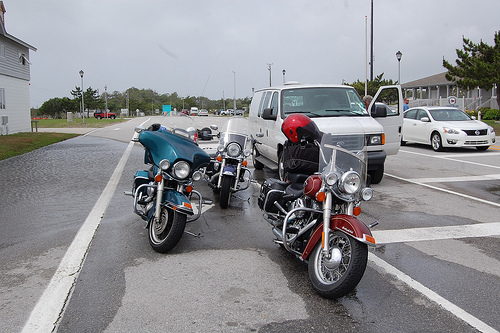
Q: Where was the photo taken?
A: It was taken at the street.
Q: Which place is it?
A: It is a street.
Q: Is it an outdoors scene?
A: Yes, it is outdoors.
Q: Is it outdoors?
A: Yes, it is outdoors.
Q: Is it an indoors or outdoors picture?
A: It is outdoors.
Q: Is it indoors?
A: No, it is outdoors.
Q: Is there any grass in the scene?
A: Yes, there is grass.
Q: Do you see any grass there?
A: Yes, there is grass.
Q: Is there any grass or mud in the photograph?
A: Yes, there is grass.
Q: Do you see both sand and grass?
A: No, there is grass but no sand.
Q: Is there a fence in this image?
A: No, there are no fences.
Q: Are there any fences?
A: No, there are no fences.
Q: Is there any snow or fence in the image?
A: No, there are no fences or snow.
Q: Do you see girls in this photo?
A: No, there are no girls.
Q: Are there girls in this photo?
A: No, there are no girls.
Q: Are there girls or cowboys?
A: No, there are no girls or cowboys.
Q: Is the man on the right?
A: Yes, the man is on the right of the image.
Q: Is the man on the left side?
A: No, the man is on the right of the image.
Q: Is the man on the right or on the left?
A: The man is on the right of the image.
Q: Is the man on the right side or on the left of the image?
A: The man is on the right of the image.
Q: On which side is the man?
A: The man is on the right of the image.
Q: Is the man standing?
A: Yes, the man is standing.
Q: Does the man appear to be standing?
A: Yes, the man is standing.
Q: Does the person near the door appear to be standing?
A: Yes, the man is standing.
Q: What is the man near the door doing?
A: The man is standing.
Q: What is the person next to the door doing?
A: The man is standing.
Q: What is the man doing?
A: The man is standing.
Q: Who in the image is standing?
A: The man is standing.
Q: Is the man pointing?
A: No, the man is standing.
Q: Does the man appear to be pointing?
A: No, the man is standing.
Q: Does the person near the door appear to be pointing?
A: No, the man is standing.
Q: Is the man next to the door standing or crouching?
A: The man is standing.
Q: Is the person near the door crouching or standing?
A: The man is standing.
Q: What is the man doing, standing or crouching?
A: The man is standing.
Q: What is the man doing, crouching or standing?
A: The man is standing.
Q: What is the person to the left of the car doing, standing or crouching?
A: The man is standing.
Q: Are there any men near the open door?
A: Yes, there is a man near the door.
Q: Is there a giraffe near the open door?
A: No, there is a man near the door.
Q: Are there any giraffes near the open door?
A: No, there is a man near the door.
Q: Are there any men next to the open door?
A: Yes, there is a man next to the door.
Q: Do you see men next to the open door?
A: Yes, there is a man next to the door.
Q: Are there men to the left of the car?
A: Yes, there is a man to the left of the car.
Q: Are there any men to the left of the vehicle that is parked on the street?
A: Yes, there is a man to the left of the car.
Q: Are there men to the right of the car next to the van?
A: No, the man is to the left of the car.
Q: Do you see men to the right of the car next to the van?
A: No, the man is to the left of the car.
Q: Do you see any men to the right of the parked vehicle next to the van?
A: No, the man is to the left of the car.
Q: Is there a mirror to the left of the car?
A: No, there is a man to the left of the car.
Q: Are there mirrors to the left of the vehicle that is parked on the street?
A: No, there is a man to the left of the car.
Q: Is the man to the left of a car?
A: Yes, the man is to the left of a car.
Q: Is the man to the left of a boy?
A: No, the man is to the left of a car.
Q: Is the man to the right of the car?
A: No, the man is to the left of the car.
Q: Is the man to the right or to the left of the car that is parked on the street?
A: The man is to the left of the car.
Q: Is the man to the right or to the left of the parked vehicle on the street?
A: The man is to the left of the car.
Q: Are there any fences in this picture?
A: No, there are no fences.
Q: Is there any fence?
A: No, there are no fences.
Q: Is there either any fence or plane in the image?
A: No, there are no fences or airplanes.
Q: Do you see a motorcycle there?
A: Yes, there is a motorcycle.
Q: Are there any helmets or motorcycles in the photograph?
A: Yes, there is a motorcycle.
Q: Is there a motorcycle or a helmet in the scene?
A: Yes, there is a motorcycle.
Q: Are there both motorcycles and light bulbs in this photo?
A: No, there is a motorcycle but no light bulbs.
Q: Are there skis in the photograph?
A: No, there are no skis.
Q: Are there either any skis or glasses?
A: No, there are no skis or glasses.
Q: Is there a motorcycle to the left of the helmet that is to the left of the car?
A: Yes, there is a motorcycle to the left of the helmet.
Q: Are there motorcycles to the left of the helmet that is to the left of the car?
A: Yes, there is a motorcycle to the left of the helmet.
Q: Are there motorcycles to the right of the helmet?
A: No, the motorcycle is to the left of the helmet.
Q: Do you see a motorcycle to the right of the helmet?
A: No, the motorcycle is to the left of the helmet.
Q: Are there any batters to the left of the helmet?
A: No, there is a motorcycle to the left of the helmet.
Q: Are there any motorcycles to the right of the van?
A: No, the motorcycle is to the left of the van.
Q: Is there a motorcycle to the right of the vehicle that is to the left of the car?
A: No, the motorcycle is to the left of the van.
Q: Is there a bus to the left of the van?
A: No, there is a motorcycle to the left of the van.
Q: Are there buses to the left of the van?
A: No, there is a motorcycle to the left of the van.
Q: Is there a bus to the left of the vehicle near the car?
A: No, there is a motorcycle to the left of the van.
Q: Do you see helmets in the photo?
A: Yes, there is a helmet.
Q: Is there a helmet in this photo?
A: Yes, there is a helmet.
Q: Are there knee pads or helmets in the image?
A: Yes, there is a helmet.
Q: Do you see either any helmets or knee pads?
A: Yes, there is a helmet.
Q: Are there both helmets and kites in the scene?
A: No, there is a helmet but no kites.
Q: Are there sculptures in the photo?
A: No, there are no sculptures.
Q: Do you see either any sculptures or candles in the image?
A: No, there are no sculptures or candles.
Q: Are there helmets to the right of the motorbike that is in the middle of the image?
A: Yes, there is a helmet to the right of the motorbike.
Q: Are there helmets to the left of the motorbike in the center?
A: No, the helmet is to the right of the motorcycle.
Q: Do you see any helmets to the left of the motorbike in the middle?
A: No, the helmet is to the right of the motorcycle.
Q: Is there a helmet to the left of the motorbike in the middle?
A: No, the helmet is to the right of the motorcycle.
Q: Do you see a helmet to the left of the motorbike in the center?
A: No, the helmet is to the right of the motorcycle.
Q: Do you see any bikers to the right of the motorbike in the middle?
A: No, there is a helmet to the right of the motorbike.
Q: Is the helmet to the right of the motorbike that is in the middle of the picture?
A: Yes, the helmet is to the right of the motorcycle.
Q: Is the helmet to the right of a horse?
A: No, the helmet is to the right of the motorcycle.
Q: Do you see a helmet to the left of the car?
A: Yes, there is a helmet to the left of the car.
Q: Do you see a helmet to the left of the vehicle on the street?
A: Yes, there is a helmet to the left of the car.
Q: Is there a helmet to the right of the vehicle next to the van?
A: No, the helmet is to the left of the car.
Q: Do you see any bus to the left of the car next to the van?
A: No, there is a helmet to the left of the car.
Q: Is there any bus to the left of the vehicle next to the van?
A: No, there is a helmet to the left of the car.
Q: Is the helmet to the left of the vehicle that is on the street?
A: Yes, the helmet is to the left of the car.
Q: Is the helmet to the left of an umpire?
A: No, the helmet is to the left of the car.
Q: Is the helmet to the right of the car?
A: No, the helmet is to the left of the car.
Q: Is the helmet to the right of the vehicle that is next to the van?
A: No, the helmet is to the left of the car.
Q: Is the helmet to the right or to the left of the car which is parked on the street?
A: The helmet is to the left of the car.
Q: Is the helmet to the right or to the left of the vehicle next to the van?
A: The helmet is to the left of the car.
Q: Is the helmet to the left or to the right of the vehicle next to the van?
A: The helmet is to the left of the car.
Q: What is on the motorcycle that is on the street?
A: The helmet is on the motorcycle.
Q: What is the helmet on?
A: The helmet is on the motorbike.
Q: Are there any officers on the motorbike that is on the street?
A: No, there is a helmet on the motorcycle.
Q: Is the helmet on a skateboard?
A: No, the helmet is on the motorbike.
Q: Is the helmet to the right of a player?
A: No, the helmet is to the right of the motorcycle.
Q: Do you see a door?
A: Yes, there is a door.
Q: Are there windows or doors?
A: Yes, there is a door.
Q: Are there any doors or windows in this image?
A: Yes, there is a door.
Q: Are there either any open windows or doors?
A: Yes, there is an open door.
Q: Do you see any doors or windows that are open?
A: Yes, the door is open.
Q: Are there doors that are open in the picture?
A: Yes, there is an open door.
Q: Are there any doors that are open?
A: Yes, there is a door that is open.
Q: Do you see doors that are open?
A: Yes, there is a door that is open.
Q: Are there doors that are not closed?
A: Yes, there is a open door.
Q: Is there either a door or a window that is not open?
A: No, there is a door but it is open.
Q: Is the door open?
A: Yes, the door is open.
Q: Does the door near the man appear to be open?
A: Yes, the door is open.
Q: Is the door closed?
A: No, the door is open.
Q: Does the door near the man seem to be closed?
A: No, the door is open.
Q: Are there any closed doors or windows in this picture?
A: No, there is a door but it is open.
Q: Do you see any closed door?
A: No, there is a door but it is open.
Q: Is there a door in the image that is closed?
A: No, there is a door but it is open.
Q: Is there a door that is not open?
A: No, there is a door but it is open.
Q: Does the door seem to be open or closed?
A: The door is open.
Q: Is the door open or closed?
A: The door is open.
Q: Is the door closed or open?
A: The door is open.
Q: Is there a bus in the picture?
A: No, there are no buses.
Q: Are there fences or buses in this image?
A: No, there are no buses or fences.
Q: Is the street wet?
A: Yes, the street is wet.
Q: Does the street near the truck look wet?
A: Yes, the street is wet.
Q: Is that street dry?
A: No, the street is wet.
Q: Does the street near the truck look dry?
A: No, the street is wet.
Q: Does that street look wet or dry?
A: The street is wet.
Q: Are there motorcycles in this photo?
A: Yes, there is a motorcycle.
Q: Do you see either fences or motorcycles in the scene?
A: Yes, there is a motorcycle.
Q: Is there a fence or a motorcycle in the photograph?
A: Yes, there is a motorcycle.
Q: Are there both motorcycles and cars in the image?
A: Yes, there are both a motorcycle and a car.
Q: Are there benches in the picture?
A: No, there are no benches.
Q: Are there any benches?
A: No, there are no benches.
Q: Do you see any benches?
A: No, there are no benches.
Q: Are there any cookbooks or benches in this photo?
A: No, there are no benches or cookbooks.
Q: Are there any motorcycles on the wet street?
A: Yes, there is a motorcycle on the street.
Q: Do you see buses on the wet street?
A: No, there is a motorcycle on the street.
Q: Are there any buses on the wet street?
A: No, there is a motorcycle on the street.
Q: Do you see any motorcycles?
A: Yes, there is a motorcycle.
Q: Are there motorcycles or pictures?
A: Yes, there is a motorcycle.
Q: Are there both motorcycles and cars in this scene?
A: Yes, there are both a motorcycle and a car.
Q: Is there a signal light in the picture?
A: No, there are no traffic lights.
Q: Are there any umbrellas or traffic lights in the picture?
A: No, there are no traffic lights or umbrellas.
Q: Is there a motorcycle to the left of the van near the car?
A: Yes, there is a motorcycle to the left of the van.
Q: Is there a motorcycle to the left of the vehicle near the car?
A: Yes, there is a motorcycle to the left of the van.